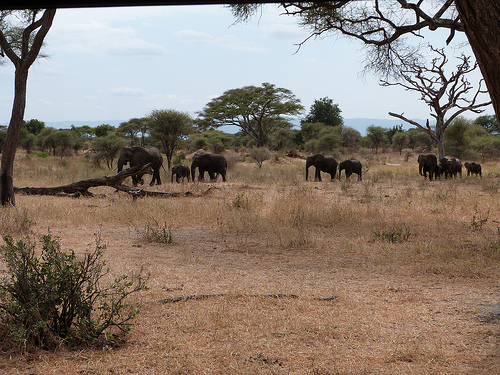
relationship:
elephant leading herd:
[112, 144, 168, 190] [170, 145, 486, 186]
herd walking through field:
[170, 145, 486, 186] [1, 150, 499, 370]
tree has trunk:
[202, 82, 306, 150] [3, 4, 65, 211]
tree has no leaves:
[385, 46, 493, 160] [381, 77, 422, 94]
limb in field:
[18, 163, 216, 199] [1, 150, 499, 370]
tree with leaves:
[202, 82, 306, 150] [281, 98, 304, 114]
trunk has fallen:
[14, 180, 98, 200] [19, 175, 219, 208]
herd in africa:
[170, 145, 486, 186] [1, 150, 499, 370]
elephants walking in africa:
[104, 130, 486, 184] [1, 150, 499, 370]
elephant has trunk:
[112, 144, 168, 190] [113, 162, 125, 196]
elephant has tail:
[112, 144, 168, 190] [161, 162, 172, 178]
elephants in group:
[104, 130, 486, 184] [170, 145, 486, 186]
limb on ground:
[18, 163, 216, 199] [1, 150, 499, 370]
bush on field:
[2, 223, 162, 357] [1, 150, 499, 370]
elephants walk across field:
[104, 130, 486, 184] [1, 150, 499, 370]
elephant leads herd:
[112, 144, 168, 190] [170, 145, 486, 186]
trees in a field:
[25, 78, 498, 158] [1, 150, 499, 370]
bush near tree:
[2, 223, 162, 357] [3, 4, 65, 211]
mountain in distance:
[44, 117, 131, 129] [7, 100, 499, 135]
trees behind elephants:
[25, 78, 498, 158] [104, 130, 486, 184]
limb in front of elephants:
[18, 166, 228, 207] [104, 130, 486, 184]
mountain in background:
[44, 117, 131, 129] [2, 12, 500, 129]